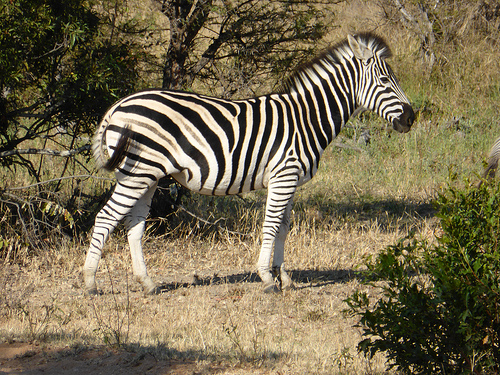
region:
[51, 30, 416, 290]
this is a zebra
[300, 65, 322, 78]
this is the fur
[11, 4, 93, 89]
this is a tree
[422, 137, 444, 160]
this is a grass area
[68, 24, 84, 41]
the tree has green leaves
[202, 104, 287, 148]
the zebra has many colors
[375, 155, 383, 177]
the grass is green in color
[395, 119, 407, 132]
the zebras mouth is black in color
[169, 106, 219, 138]
the zebra is black and white in color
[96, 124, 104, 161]
this is the tail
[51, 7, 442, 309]
zebra moving on flat ground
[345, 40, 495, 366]
bush with dark green leaves in front of zebra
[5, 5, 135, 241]
bushes and grasses in back of zebra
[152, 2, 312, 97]
tree trunk and dark branches behind zebra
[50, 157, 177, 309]
rear legs a few inches apart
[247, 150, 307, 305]
front legs close together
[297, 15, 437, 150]
head slightly turned to right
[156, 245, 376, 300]
thin shadow underneath zebra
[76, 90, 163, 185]
tail curled to one side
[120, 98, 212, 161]
light grey stripes between black and white stripes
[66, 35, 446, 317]
a full grown zebra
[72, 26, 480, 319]
a black and white animal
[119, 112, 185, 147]
a faded grey stripe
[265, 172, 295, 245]
narrow black stripes on leg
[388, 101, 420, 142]
an animals black muzzle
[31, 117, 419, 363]
a dry overgrown field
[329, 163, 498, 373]
a dark green plant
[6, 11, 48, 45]
some small dark leaves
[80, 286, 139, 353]
a few bare branches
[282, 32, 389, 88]
a short mane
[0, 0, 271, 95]
these are trees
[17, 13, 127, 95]
the tree leafs are green in color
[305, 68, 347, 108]
this is the zebras fur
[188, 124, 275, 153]
the zebras fur is black and white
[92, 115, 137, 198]
this is the zebras tail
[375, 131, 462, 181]
this the grass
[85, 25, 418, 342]
the zebra is looking at somthing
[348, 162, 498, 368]
this is a shrub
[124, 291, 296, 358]
this is a dry grass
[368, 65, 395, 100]
this is the zebras eye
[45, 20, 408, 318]
A zebra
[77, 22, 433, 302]
A zebra standing up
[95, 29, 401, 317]
A zebra standing in brown grass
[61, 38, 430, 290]
A white zebra with black stripes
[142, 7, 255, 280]
A tree behind a zebra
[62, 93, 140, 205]
The tail of a zebra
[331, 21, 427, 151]
The head of a zebra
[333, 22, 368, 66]
The ear of a zebra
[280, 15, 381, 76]
The mane of a zebra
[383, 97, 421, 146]
The nose of a zebra